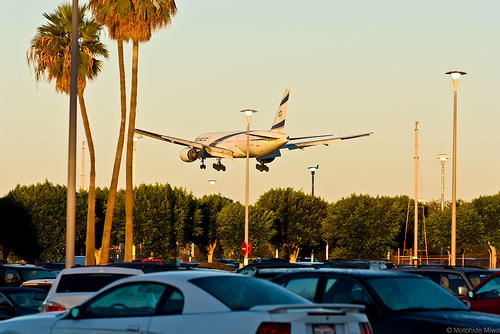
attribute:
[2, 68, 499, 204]
clouds — white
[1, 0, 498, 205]
sky — blue, clear and cloudless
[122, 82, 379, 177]
plane — large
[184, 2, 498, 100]
sky — blue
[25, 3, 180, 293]
palmtrees — tall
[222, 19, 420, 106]
sky — blue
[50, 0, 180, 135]
fronds — rounded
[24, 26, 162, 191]
tree — coconut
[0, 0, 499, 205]
clouds — white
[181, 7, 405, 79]
sky — blue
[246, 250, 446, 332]
car — blue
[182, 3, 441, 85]
sky — blue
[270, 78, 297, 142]
tail — blue , white 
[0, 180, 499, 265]
trees — green, round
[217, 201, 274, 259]
tree — green 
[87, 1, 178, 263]
tree — coconut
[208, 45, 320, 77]
sky — pale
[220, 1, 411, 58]
sky — blue, orange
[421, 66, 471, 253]
lamp — tall, street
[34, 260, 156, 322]
car — white 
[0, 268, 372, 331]
sedan — white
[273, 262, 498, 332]
vehicle — dark colored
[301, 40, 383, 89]
clouds — white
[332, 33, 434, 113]
clouds — white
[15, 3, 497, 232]
clouds — white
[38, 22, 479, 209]
sky — blue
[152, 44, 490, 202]
sky — blue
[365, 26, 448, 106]
clouds — white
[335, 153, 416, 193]
clouds — white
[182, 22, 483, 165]
sky — blue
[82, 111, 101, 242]
trunk — bent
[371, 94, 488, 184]
clouds — white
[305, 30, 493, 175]
clouds — white